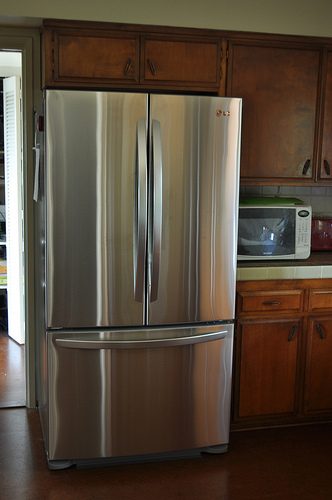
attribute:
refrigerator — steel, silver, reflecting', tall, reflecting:
[33, 90, 246, 471]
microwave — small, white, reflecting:
[240, 198, 312, 262]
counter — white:
[239, 258, 332, 284]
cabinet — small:
[41, 19, 229, 96]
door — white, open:
[1, 48, 33, 411]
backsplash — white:
[241, 182, 332, 218]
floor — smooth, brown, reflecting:
[3, 410, 332, 500]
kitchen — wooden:
[0, 0, 331, 499]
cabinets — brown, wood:
[233, 281, 331, 428]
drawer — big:
[41, 324, 237, 463]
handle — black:
[287, 323, 297, 343]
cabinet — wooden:
[226, 31, 322, 187]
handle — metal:
[150, 120, 162, 305]